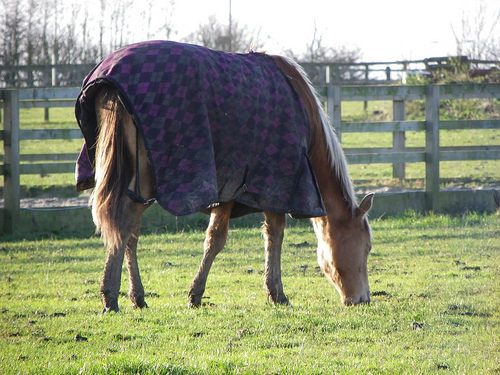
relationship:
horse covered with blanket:
[64, 36, 382, 311] [100, 44, 314, 219]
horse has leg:
[64, 36, 382, 311] [204, 209, 235, 295]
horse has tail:
[64, 36, 382, 311] [87, 111, 138, 232]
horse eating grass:
[64, 36, 382, 311] [242, 310, 288, 332]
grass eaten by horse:
[242, 310, 288, 332] [64, 36, 382, 311]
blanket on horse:
[100, 44, 314, 219] [64, 36, 382, 311]